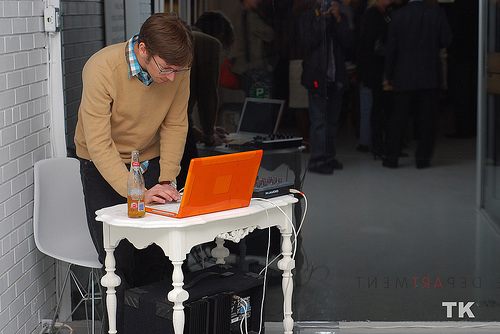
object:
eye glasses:
[149, 53, 189, 74]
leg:
[276, 224, 297, 334]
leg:
[96, 244, 123, 334]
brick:
[0, 54, 17, 70]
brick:
[13, 86, 30, 103]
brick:
[28, 261, 47, 283]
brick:
[29, 291, 46, 314]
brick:
[25, 17, 41, 31]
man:
[71, 12, 191, 333]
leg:
[167, 252, 187, 332]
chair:
[33, 156, 102, 334]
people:
[227, 0, 454, 175]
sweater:
[73, 40, 190, 202]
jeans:
[304, 81, 338, 170]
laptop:
[141, 149, 264, 219]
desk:
[94, 193, 298, 334]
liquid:
[127, 195, 146, 218]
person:
[378, 0, 448, 170]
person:
[299, 0, 348, 174]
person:
[344, 0, 387, 150]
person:
[182, 11, 233, 163]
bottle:
[128, 162, 146, 218]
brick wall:
[1, 0, 106, 332]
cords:
[248, 187, 311, 242]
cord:
[250, 203, 272, 334]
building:
[0, 0, 204, 334]